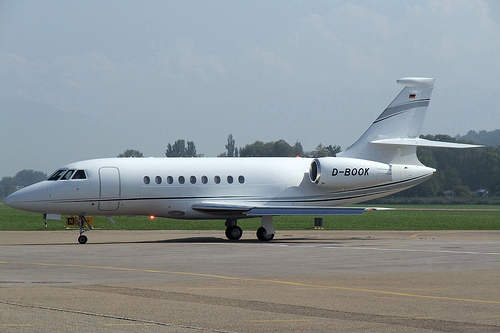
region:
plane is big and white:
[18, 99, 458, 296]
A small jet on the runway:
[7, 53, 487, 272]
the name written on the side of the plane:
[325, 163, 381, 183]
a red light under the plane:
[142, 209, 162, 229]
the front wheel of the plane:
[70, 213, 105, 255]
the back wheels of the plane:
[220, 212, 293, 243]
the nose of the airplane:
[4, 171, 47, 233]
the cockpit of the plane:
[4, 157, 127, 233]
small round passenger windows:
[136, 167, 268, 192]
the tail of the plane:
[327, 63, 472, 197]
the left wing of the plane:
[184, 191, 400, 234]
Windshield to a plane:
[41, 153, 106, 194]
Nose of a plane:
[1, 150, 71, 249]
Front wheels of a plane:
[61, 218, 108, 250]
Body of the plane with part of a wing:
[108, 125, 306, 232]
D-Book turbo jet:
[297, 134, 399, 192]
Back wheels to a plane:
[203, 220, 314, 257]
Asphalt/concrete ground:
[68, 251, 386, 308]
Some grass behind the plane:
[403, 203, 493, 225]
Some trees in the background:
[166, 141, 316, 156]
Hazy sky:
[40, 20, 380, 105]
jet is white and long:
[3, 122, 440, 242]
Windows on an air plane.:
[121, 167, 268, 202]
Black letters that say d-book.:
[308, 162, 398, 197]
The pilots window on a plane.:
[28, 155, 103, 201]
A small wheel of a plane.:
[46, 220, 112, 258]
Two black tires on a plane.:
[201, 210, 301, 253]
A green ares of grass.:
[338, 199, 488, 243]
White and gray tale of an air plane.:
[316, 66, 461, 157]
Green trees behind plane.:
[121, 113, 342, 180]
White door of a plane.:
[81, 154, 134, 227]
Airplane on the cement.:
[46, 72, 448, 330]